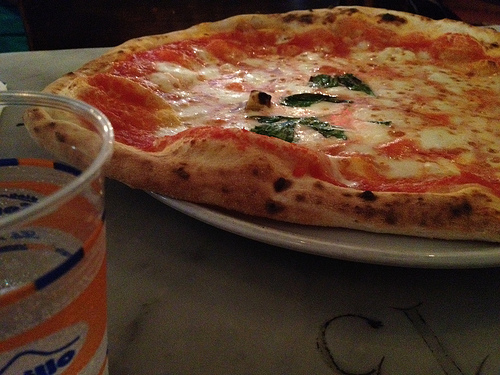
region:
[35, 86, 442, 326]
a pizza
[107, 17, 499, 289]
a pizza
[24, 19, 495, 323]
a cheese pizza on plate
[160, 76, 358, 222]
the pizza was cooked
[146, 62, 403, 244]
pizza has been baked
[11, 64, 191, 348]
a plastic cup of water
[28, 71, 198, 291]
the cup is orange and blue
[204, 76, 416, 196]
there is basil on this pizza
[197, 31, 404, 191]
the cheese is white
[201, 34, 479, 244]
tomato sauce is red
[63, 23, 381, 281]
the plate is round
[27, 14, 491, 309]
this is a pizza for one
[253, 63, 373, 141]
fresh basil leaves on a pizza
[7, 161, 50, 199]
clear sparkling liquid in a cup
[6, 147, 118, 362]
a blue orange and clear cup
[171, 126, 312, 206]
a bubble in the pizza crust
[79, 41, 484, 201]
a cheese and basil pizza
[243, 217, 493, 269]
the edge of a metal pizza pan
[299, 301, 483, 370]
the letter CL on the top of a table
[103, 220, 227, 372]
a white and gray marble table top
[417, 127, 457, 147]
toasted white cheese on a pizza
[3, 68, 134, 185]
a crust of pizza behind a clear cup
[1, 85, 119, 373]
A clear, plastic cup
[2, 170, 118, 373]
A clear, bubbly soda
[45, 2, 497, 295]
A small cheese pizza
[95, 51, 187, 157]
Red, pizza sauce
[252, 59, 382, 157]
Cooked basil leaves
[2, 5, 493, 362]
An easy, late night dinner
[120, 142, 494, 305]
A white, porcelain plate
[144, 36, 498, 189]
Melted, mozzerella cheese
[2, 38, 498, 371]
Fancy, printed cloth table cloth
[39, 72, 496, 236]
Thin, crispy pizza crust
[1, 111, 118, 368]
cup of water on table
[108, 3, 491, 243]
pizza on silver dish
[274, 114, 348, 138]
green vegetable on pizza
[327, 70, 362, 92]
green vegetable on pizza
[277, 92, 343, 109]
green vegetable on pizza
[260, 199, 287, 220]
burnt part on crust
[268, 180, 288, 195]
burnt part on crust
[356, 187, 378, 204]
burnt part on crust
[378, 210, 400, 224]
burnt part on crust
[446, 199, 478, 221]
burnt part on crust